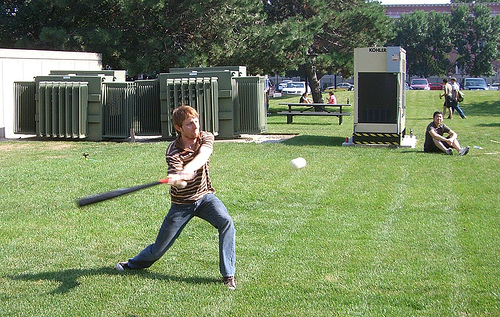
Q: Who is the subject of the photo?
A: The batter.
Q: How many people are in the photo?
A: 6.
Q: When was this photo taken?
A: During the day.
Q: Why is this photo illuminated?
A: Sunlight.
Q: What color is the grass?
A: Green.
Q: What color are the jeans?
A: Blue.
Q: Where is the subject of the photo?
A: In the grass.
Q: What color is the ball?
A: White.